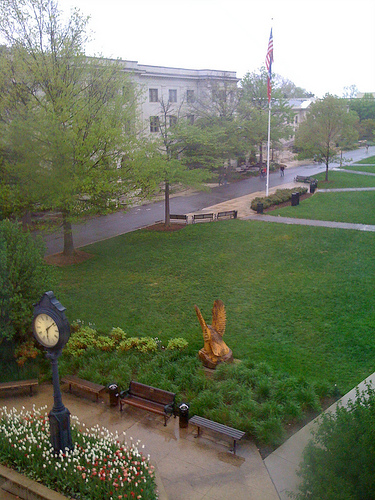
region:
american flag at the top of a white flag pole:
[262, 13, 274, 195]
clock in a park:
[28, 283, 73, 452]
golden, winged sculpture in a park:
[186, 297, 236, 365]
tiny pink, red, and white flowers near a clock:
[2, 403, 156, 496]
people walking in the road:
[215, 161, 290, 189]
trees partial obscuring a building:
[0, 41, 237, 201]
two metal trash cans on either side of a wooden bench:
[107, 376, 189, 436]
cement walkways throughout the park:
[250, 152, 372, 498]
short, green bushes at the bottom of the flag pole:
[249, 184, 307, 210]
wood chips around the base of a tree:
[41, 242, 97, 269]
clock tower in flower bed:
[10, 281, 133, 495]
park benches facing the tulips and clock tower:
[0, 284, 252, 491]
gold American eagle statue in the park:
[160, 289, 271, 389]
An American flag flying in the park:
[254, 11, 292, 211]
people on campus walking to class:
[210, 157, 296, 190]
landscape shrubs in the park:
[74, 317, 311, 409]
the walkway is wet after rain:
[83, 401, 273, 498]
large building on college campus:
[15, 37, 263, 202]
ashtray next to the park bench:
[103, 377, 181, 438]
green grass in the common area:
[95, 230, 373, 333]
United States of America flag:
[265, 12, 278, 66]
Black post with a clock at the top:
[28, 286, 84, 453]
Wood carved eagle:
[191, 292, 236, 380]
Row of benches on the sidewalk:
[175, 210, 241, 225]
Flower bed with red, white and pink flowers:
[76, 430, 151, 495]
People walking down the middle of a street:
[246, 160, 295, 181]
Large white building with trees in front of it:
[89, 54, 234, 189]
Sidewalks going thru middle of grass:
[338, 178, 372, 241]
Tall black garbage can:
[175, 398, 188, 433]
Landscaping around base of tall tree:
[50, 237, 100, 271]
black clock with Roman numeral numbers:
[25, 278, 83, 456]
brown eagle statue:
[186, 282, 240, 373]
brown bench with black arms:
[119, 370, 177, 427]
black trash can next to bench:
[176, 398, 190, 432]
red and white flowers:
[2, 405, 147, 496]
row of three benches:
[167, 207, 243, 224]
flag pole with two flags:
[264, 33, 276, 190]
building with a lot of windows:
[14, 48, 257, 164]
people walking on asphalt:
[257, 162, 288, 179]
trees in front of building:
[177, 87, 285, 176]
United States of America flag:
[249, 15, 280, 107]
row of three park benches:
[170, 207, 242, 224]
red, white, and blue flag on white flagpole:
[250, 15, 288, 200]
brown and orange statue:
[175, 298, 253, 369]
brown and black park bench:
[113, 373, 178, 420]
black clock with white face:
[18, 285, 85, 460]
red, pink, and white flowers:
[0, 407, 160, 489]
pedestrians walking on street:
[219, 164, 290, 179]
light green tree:
[2, 2, 171, 258]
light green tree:
[292, 92, 363, 186]